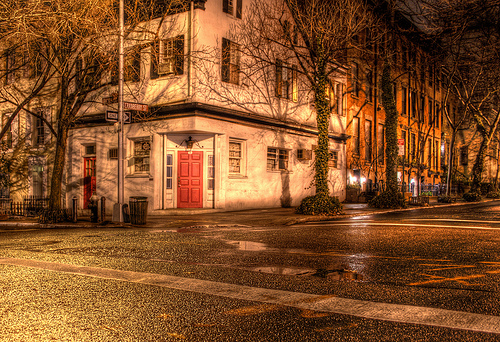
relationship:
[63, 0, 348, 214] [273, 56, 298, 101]
building has window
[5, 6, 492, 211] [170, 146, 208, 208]
apartment building has door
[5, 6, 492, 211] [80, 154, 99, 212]
apartment building has door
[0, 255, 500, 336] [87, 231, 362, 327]
line marking crosswalk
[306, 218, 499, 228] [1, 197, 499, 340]
yellow line painted on road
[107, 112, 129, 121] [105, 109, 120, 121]
arrow in arrow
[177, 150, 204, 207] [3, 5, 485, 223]
door closed on building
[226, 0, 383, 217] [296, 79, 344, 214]
tree with vines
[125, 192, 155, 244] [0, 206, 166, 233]
trash can on sidewalk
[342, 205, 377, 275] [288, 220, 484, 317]
glare on street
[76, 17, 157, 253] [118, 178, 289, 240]
pole on sidewalk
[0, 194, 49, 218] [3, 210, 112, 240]
fence on sidewalk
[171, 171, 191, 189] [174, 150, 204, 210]
knob on door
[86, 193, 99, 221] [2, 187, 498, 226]
fire hydrant on sidewalk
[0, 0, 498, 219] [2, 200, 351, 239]
buildings across street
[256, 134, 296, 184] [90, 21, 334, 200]
window in building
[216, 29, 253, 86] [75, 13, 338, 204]
window in building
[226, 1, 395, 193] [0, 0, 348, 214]
tree in front of building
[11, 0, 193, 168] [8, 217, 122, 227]
trees on sidewalk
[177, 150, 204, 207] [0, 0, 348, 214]
door on front of building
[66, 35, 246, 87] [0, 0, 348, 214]
windows on side of building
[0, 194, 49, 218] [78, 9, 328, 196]
fence by building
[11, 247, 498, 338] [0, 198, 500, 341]
line on lit road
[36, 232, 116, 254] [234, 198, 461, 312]
puddles on street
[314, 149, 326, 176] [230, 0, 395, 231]
leaves growing on side of tree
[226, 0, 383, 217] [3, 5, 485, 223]
tree by building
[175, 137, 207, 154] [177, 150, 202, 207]
light above door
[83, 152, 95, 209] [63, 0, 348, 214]
door on side of building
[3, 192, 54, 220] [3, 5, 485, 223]
fence beside building